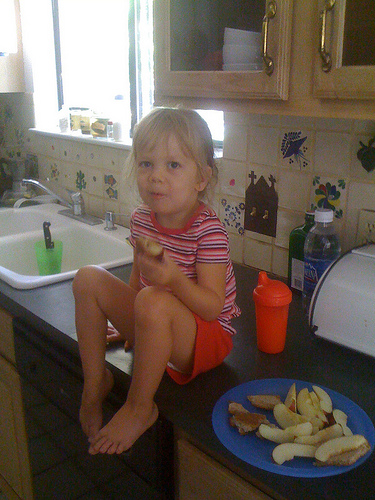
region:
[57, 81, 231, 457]
little girl wearing stripped shirt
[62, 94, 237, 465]
little girl wearing red shorts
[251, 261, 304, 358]
red cup with top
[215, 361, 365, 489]
plate with apple slices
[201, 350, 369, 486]
plate with pieces of bread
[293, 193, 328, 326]
water bottle with water in it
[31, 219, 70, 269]
green cup in sink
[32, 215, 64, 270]
black knife in green cup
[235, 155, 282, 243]
castle light switch plate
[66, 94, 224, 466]
little girl eating food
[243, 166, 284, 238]
a church shaped switch cover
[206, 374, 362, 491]
a blue plate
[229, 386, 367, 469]
sliced red apples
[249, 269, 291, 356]
a bright red sippy cup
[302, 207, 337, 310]
a bottle of Aquafina water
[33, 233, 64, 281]
a green plastic cup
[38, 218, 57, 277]
a knife with a black handle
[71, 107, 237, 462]
a child sitting on the kitchen counter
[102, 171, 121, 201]
a tile with two fish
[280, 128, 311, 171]
a tile with a blue bird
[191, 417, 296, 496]
A blue plate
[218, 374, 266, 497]
A blue plate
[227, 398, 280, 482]
A blue plate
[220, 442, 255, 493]
A blue plate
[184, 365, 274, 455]
A blue plate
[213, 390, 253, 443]
A blue plate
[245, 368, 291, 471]
A blue plate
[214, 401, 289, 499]
A plate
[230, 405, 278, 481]
A plate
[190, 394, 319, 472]
A plate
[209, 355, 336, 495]
A plate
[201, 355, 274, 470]
A plate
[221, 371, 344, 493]
A blue plate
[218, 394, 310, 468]
A blue plate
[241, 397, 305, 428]
A blue plate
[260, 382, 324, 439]
A blue plate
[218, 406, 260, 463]
A blue plate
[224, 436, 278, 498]
A blue plate